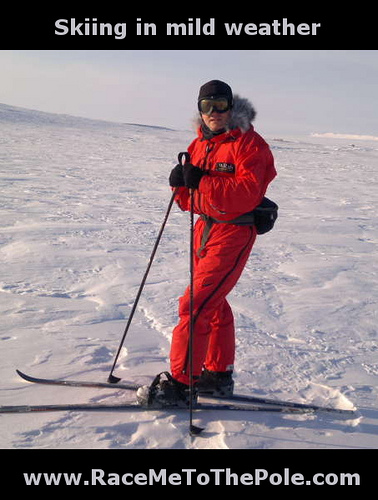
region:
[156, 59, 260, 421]
skier in red outfit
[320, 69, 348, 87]
white clouds n blue sky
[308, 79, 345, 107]
white clouds n blue sky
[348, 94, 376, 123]
white clouds n blue sky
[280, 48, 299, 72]
white clouds n blue sky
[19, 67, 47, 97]
white clouds n blue sky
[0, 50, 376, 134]
light in daytime sky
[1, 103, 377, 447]
snow covered surface of ground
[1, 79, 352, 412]
man standing on two skis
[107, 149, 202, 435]
two poles in gloved hands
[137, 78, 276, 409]
man in red snowsuit with stripe on leg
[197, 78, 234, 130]
hat and goggles on head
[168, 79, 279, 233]
bag attached to man's waist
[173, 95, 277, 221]
fur lined hood on coat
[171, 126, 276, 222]
jacket with emblem on chest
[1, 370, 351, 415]
boots attached to two skis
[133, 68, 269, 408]
skier wearing red outfit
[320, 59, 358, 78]
white clouds in blue sky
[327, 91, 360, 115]
white clouds in blue sky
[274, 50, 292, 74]
white clouds in blue sky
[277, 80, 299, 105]
white clouds in blue sky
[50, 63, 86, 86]
white clouds in blue sky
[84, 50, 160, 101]
white clouds in blue sky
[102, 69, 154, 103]
white clouds in blue sky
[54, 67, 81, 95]
white clouds in blue sky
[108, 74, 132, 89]
white clouds in blue sky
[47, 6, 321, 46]
skiing mild in the winter sign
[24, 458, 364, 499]
race me to the pole website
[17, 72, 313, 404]
skier posing for a photo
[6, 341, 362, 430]
skis on the skiers feet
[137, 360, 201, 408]
snow shoes on the guy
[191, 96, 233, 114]
goggles on the guys face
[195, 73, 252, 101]
cap on the guys head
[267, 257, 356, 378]
tracks in the white snow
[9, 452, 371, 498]
www address in black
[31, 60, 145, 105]
blue sky in the distance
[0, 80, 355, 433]
skier in red snow suit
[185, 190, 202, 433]
a skier's left ski pole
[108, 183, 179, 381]
a skier's right ski pole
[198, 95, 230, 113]
a skier's ski goggles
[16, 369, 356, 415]
a skier's right ski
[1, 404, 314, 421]
a skier's left ski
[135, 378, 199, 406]
a skier's left boot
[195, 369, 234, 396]
a skier's right boot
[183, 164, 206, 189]
a skier's left hand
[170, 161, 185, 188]
a skier's right hand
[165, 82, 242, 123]
man has black hat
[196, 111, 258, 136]
man has fur hood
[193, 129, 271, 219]
man has orange coat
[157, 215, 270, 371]
black and orange pants